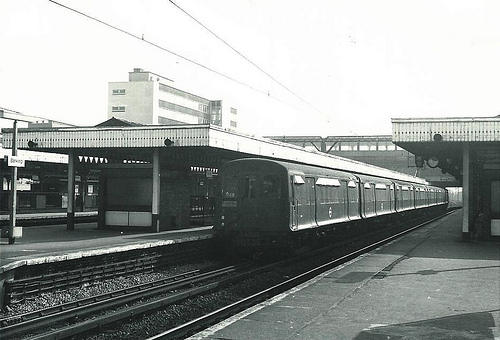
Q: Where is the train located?
A: Train tracks.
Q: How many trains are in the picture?
A: One.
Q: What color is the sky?
A: White.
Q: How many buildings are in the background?
A: One.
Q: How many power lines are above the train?
A: Two.